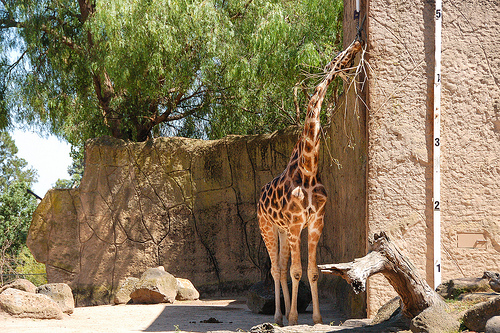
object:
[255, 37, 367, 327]
giraffe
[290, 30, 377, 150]
branch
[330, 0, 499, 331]
wall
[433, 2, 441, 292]
measuring stick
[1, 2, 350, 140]
tree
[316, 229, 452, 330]
tree stump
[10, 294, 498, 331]
ground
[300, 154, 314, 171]
spot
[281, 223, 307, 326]
leg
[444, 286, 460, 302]
moss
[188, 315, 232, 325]
poop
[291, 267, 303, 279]
knee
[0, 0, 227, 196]
sky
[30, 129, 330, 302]
wall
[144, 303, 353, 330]
shadow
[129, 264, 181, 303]
rock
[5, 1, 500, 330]
zoo